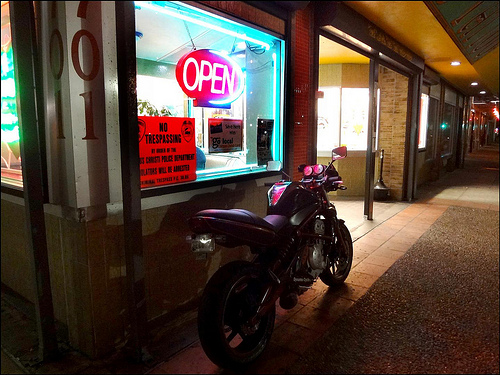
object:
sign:
[138, 115, 197, 190]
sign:
[174, 47, 245, 107]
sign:
[208, 118, 243, 153]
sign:
[258, 117, 274, 166]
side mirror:
[330, 145, 347, 161]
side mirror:
[266, 160, 281, 171]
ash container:
[370, 147, 391, 202]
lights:
[489, 108, 499, 119]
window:
[341, 88, 378, 151]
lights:
[417, 92, 429, 150]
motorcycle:
[186, 146, 352, 368]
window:
[134, 0, 284, 190]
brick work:
[377, 63, 408, 200]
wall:
[377, 63, 409, 198]